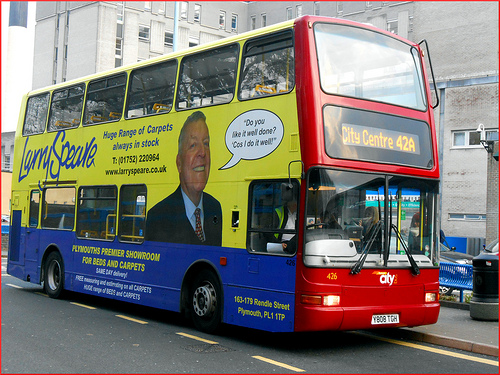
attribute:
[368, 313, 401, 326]
license plate — black, white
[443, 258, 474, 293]
bench — Blue 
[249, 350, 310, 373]
line — yellow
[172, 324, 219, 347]
line — yellow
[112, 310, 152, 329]
line — yellow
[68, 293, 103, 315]
line — yellow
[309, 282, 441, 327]
light — on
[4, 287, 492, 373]
road — Black , asphalt  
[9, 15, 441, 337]
bus — yellow, red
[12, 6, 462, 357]
bus — yellow